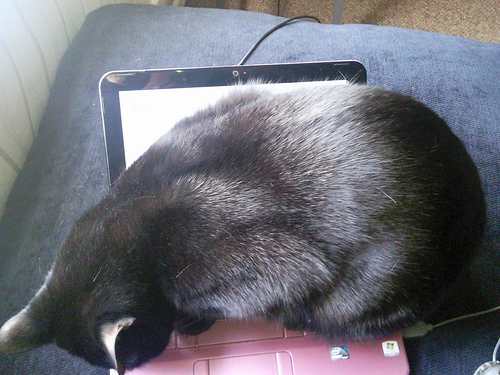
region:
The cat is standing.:
[27, 110, 493, 332]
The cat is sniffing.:
[28, 87, 483, 372]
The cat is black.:
[8, 100, 438, 366]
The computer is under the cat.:
[56, 60, 417, 371]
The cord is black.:
[210, 3, 316, 70]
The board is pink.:
[125, 305, 300, 371]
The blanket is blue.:
[133, 13, 248, 69]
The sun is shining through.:
[10, 1, 491, 324]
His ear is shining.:
[71, 285, 153, 374]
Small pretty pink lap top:
[92, 72, 414, 374]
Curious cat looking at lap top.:
[17, 234, 157, 374]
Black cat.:
[29, 110, 495, 374]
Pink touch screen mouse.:
[190, 350, 297, 373]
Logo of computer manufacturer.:
[376, 337, 404, 362]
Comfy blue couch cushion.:
[82, 11, 235, 68]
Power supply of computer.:
[239, 4, 326, 61]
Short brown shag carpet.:
[382, 5, 498, 34]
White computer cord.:
[407, 312, 498, 329]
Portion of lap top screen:
[104, 71, 229, 141]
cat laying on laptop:
[4, 76, 488, 371]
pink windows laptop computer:
[178, 339, 418, 371]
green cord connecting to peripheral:
[404, 300, 496, 355]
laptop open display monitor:
[89, 66, 166, 138]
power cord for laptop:
[214, 10, 346, 64]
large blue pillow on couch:
[389, 27, 491, 100]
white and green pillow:
[3, 9, 81, 181]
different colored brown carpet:
[411, 3, 493, 33]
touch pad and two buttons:
[187, 353, 321, 372]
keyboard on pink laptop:
[178, 331, 320, 343]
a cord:
[237, 14, 309, 55]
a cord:
[254, 4, 304, 46]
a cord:
[238, 24, 306, 82]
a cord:
[241, 11, 283, 46]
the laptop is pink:
[299, 353, 314, 373]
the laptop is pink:
[307, 350, 321, 374]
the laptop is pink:
[304, 343, 315, 372]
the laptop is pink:
[304, 358, 315, 373]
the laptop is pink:
[311, 341, 323, 373]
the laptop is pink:
[311, 350, 318, 372]